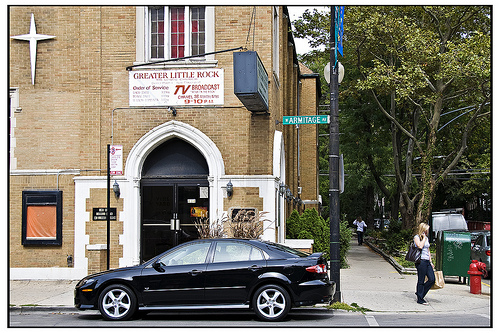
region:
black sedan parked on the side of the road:
[65, 237, 346, 322]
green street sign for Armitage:
[273, 111, 340, 130]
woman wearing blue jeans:
[406, 212, 443, 309]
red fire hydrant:
[463, 250, 488, 300]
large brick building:
[16, 0, 336, 274]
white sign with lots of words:
[121, 66, 233, 111]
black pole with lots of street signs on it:
[309, 0, 359, 307]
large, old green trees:
[341, 0, 498, 247]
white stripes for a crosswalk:
[358, 301, 498, 324]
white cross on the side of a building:
[6, 9, 68, 91]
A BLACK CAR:
[49, 231, 350, 324]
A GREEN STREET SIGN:
[271, 100, 338, 140]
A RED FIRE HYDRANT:
[457, 253, 492, 303]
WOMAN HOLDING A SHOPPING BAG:
[402, 218, 457, 306]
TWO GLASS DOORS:
[127, 173, 216, 267]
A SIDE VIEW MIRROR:
[145, 255, 171, 277]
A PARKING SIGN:
[96, 139, 128, 269]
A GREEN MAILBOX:
[434, 226, 479, 287]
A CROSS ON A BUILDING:
[9, 8, 69, 92]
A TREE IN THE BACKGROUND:
[350, 26, 470, 225]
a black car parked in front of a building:
[71, 230, 338, 322]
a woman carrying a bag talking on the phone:
[406, 220, 449, 302]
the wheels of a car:
[96, 282, 293, 322]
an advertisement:
[126, 66, 226, 108]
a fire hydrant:
[465, 257, 488, 297]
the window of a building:
[20, 188, 62, 250]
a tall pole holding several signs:
[324, 7, 349, 309]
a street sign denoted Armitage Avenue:
[279, 114, 331, 126]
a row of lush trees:
[306, 9, 491, 234]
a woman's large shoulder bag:
[406, 240, 421, 263]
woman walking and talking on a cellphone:
[404, 216, 444, 315]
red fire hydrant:
[466, 252, 488, 292]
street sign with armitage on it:
[273, 107, 338, 133]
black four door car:
[66, 234, 342, 331]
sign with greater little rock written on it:
[117, 61, 224, 108]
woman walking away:
[349, 208, 369, 248]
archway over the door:
[123, 115, 232, 181]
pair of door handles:
[168, 213, 184, 235]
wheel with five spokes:
[245, 280, 291, 323]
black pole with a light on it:
[321, 47, 351, 305]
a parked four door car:
[69, 237, 339, 332]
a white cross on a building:
[14, 15, 55, 85]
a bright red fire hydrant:
[467, 252, 487, 298]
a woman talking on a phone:
[408, 219, 445, 308]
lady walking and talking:
[404, 218, 449, 316]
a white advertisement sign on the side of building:
[122, 62, 229, 109]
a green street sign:
[277, 109, 337, 130]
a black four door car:
[71, 234, 342, 324]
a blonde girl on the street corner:
[401, 213, 446, 303]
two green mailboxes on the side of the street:
[432, 230, 479, 288]